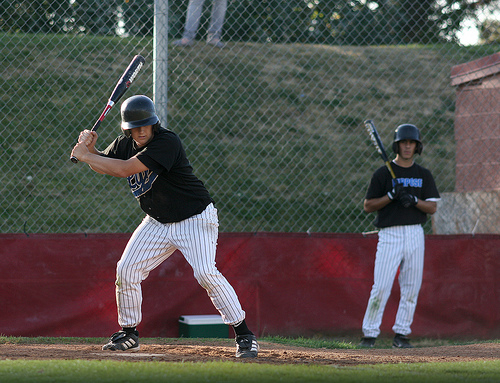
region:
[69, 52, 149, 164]
baseball bat in man's hands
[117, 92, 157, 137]
helmet on player's head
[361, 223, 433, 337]
jersey pants on man's legs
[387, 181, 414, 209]
black gloves on player's hands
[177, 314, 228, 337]
green ice chest on ground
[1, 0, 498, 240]
chain link fence around ballpark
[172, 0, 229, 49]
legs of spectator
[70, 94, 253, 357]
batter with eyes close to home plate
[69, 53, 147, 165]
an aluminum bat in the batter's hand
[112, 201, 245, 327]
striped baseball pants on the batter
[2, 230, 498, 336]
a pad to keep baseballs from getting damaged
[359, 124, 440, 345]
player in the on deck circle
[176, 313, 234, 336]
green and white case on the ground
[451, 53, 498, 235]
a part of a small building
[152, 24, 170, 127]
fence post supporting the back stop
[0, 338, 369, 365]
the dirt of the batter's boxes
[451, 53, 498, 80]
composition roofing on the building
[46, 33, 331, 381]
a man playing baseball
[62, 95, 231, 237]
man wearing black shirt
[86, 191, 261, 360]
man wearing white pants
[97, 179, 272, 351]
pants have black stripes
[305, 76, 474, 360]
man standing in background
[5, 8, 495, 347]
metal fence in background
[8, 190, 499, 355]
red trim on fence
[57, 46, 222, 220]
man holding a bat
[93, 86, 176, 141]
man wearing a baseball helmet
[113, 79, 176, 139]
baseball helmet is black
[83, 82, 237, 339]
man in black and white uniform holding bat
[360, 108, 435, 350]
man in black and white uniform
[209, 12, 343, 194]
chain link fence behind players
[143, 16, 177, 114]
support pole of fencing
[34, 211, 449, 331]
red base wall for fencing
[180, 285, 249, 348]
green and white drink cooler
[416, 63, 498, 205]
edge of brown bricked building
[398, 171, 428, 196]
blue writing on man's uniform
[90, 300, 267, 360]
black shoes with white stripes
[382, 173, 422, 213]
black and white gloves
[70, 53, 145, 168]
metal black and red baseball bat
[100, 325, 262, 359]
black and white baseball shoes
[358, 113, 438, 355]
man holding a metal bat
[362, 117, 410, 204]
black and gold bat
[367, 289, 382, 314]
green grass stain on pants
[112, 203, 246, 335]
white pants with black pinstripes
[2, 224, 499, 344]
red tarp along a fence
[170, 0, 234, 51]
gray pants and shoes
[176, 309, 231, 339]
white and green cooler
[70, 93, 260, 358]
man wearing a black jersey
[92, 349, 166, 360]
part of a white base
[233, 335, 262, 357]
a black and white shoe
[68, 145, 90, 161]
the hand of a man